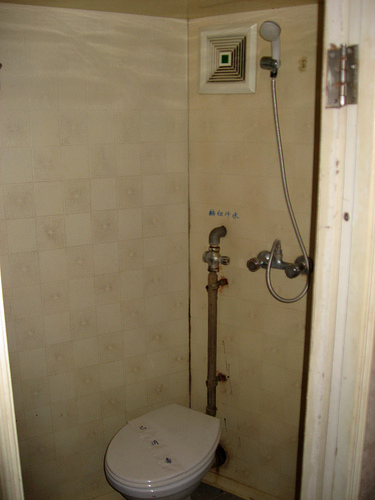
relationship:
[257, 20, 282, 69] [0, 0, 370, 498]
shower head hanging on wall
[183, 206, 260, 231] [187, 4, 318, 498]
writing on wall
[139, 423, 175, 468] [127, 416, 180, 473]
writing on lid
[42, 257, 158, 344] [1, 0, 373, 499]
tiles are on bathroom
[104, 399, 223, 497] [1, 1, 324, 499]
toilet in bathroom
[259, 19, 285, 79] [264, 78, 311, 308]
shower head attached to piping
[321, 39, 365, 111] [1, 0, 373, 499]
hinge leading to bathroom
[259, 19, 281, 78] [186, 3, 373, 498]
shower head hanging on wall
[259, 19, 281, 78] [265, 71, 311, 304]
shower head has hose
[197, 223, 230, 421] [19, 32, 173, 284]
pipe on wall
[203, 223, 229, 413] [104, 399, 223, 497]
waterpipe by toilet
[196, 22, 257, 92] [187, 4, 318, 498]
vent in wall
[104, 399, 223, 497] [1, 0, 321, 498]
toilet on wall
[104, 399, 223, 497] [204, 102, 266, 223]
toilet on wall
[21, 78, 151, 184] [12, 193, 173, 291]
wall has tile design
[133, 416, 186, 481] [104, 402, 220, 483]
sign on lid